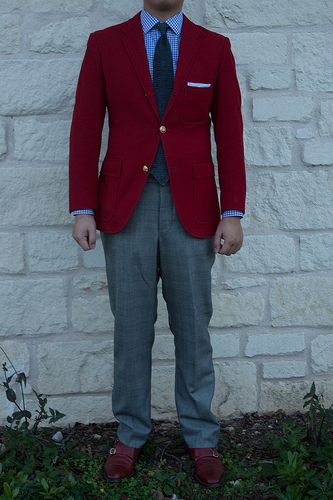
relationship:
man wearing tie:
[68, 3, 246, 486] [152, 19, 172, 191]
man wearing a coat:
[68, 3, 246, 486] [68, 11, 247, 242]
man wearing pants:
[68, 3, 246, 486] [101, 174, 220, 450]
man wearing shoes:
[68, 3, 246, 486] [101, 441, 227, 488]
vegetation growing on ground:
[0, 346, 328, 498] [3, 408, 331, 499]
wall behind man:
[0, 3, 331, 428] [68, 3, 246, 486]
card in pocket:
[186, 81, 214, 88] [186, 85, 213, 111]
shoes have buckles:
[101, 441, 227, 488] [105, 447, 222, 459]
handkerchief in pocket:
[186, 81, 214, 88] [186, 85, 213, 111]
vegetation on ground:
[0, 346, 328, 498] [3, 408, 331, 499]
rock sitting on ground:
[50, 431, 65, 446] [3, 408, 331, 499]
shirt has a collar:
[138, 8, 183, 81] [138, 8, 184, 37]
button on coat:
[157, 125, 168, 133] [68, 11, 247, 242]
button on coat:
[138, 163, 150, 173] [68, 11, 247, 242]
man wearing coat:
[68, 3, 246, 486] [68, 11, 247, 242]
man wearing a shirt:
[68, 3, 246, 486] [138, 8, 183, 81]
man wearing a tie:
[68, 3, 246, 486] [152, 19, 172, 191]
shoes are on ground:
[101, 441, 227, 488] [3, 408, 331, 499]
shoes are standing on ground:
[101, 441, 227, 488] [3, 408, 331, 499]